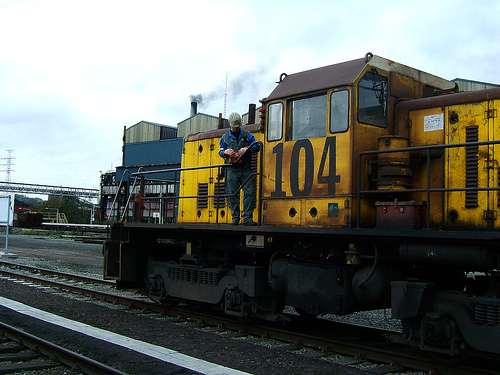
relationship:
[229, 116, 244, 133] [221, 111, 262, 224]
head of man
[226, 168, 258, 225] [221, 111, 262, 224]
legs of man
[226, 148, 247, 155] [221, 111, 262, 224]
hands of man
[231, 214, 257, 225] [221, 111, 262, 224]
feet of man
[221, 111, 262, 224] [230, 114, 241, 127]
man wearing hat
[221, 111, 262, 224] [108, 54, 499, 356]
man standing on train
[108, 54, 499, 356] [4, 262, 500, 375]
train on top of tracks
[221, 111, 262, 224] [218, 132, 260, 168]
man wearing shirt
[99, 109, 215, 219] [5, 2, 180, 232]
building in background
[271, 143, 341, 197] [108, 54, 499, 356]
numbers on side of train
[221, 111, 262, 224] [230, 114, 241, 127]
man has hat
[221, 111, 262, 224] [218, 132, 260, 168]
man has shirt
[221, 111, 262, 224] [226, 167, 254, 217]
man has pants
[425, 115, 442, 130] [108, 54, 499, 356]
notice on side of train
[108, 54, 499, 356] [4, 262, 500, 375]
train sitting on tracks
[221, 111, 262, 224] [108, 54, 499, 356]
man on top of train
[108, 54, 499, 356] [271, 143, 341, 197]
train with numbers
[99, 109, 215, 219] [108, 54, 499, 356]
building behind train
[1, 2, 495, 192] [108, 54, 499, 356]
sky above train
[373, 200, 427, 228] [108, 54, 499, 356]
box sitting on train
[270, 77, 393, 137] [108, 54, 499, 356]
window on side of train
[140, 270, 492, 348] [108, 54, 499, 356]
wheels of train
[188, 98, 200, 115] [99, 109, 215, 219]
smoke stack on top of building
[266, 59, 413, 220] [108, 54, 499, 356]
booth on middle of train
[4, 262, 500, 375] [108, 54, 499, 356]
tracks with train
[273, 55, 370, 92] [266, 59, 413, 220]
roof of booth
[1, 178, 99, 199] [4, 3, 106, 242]
bridge in background